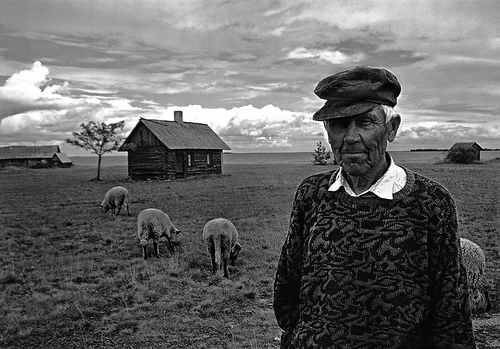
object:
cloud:
[0, 59, 95, 107]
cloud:
[2, 106, 72, 133]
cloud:
[112, 101, 236, 130]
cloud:
[279, 39, 364, 67]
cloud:
[405, 120, 497, 147]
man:
[274, 65, 475, 347]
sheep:
[458, 238, 493, 320]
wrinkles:
[371, 131, 385, 160]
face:
[321, 103, 385, 175]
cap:
[311, 67, 400, 121]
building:
[0, 145, 72, 168]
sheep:
[97, 186, 131, 216]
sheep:
[137, 209, 183, 260]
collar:
[325, 153, 398, 200]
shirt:
[329, 155, 409, 200]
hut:
[445, 142, 481, 162]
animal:
[201, 216, 242, 276]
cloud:
[201, 90, 308, 139]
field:
[3, 150, 496, 347]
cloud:
[157, 6, 295, 112]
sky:
[3, 0, 500, 156]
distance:
[3, 5, 482, 162]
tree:
[64, 119, 137, 179]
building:
[118, 110, 229, 181]